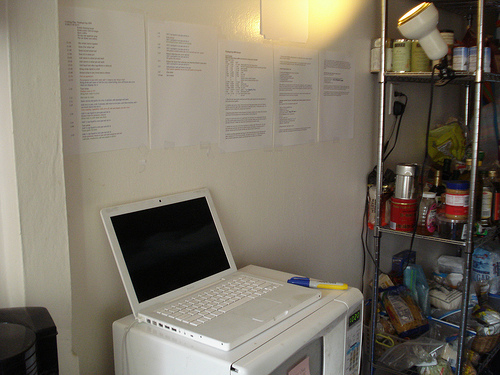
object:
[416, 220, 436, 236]
sauce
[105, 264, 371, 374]
microwave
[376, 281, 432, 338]
bag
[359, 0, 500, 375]
rack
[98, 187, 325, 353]
laptop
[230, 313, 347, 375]
door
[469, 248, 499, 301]
sack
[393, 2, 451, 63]
flood light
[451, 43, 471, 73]
cans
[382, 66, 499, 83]
shelf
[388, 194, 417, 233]
can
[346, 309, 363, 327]
display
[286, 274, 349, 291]
pen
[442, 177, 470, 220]
jar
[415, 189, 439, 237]
bottle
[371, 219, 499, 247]
rack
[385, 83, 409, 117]
power outlet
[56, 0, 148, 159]
papers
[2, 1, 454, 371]
wall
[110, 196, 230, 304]
screen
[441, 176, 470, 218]
food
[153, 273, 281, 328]
key pad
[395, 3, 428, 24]
bulb